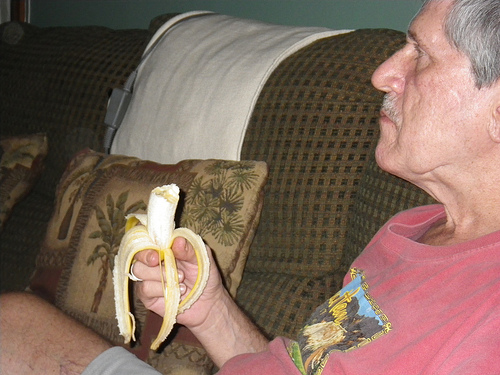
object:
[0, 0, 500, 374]
man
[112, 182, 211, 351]
banana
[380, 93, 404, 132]
facial hair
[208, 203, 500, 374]
shirt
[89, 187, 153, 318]
palm tree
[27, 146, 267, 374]
pillow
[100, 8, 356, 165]
blanket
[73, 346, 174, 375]
shorts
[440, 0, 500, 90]
hair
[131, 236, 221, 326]
hand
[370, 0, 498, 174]
face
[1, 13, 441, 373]
couch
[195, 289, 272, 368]
right arm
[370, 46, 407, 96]
nose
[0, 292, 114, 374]
bare leg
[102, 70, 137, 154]
remote control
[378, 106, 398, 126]
mouth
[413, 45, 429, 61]
eye